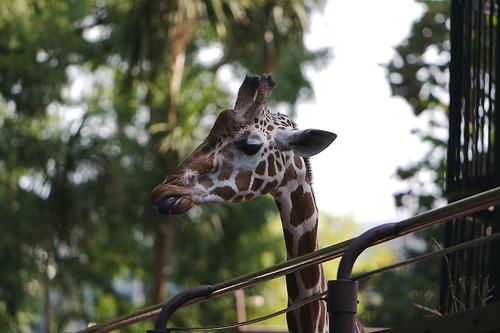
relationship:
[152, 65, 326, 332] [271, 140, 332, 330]
animal has neck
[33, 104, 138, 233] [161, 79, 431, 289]
leaf in front of giraffe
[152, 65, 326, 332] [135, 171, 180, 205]
animal has nose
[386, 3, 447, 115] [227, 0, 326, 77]
leaves on trees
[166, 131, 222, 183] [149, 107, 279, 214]
strip on face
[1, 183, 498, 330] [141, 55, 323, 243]
fene under giraffe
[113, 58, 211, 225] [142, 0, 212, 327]
stem of tree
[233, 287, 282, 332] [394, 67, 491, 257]
wood piece next to cage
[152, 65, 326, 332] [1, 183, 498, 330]
animal looking over fene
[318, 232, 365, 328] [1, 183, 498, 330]
pole of fene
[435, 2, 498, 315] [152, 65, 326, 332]
cage behind animal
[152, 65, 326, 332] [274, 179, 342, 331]
animal has neck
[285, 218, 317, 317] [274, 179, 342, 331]
brown spots on neck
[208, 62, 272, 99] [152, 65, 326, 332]
horn on animal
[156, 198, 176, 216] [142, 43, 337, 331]
black tongue sticking out of giraffe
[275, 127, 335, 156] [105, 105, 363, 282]
ear of giraffe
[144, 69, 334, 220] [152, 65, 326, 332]
head of animal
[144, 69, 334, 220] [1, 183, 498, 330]
head over fene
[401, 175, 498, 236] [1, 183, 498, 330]
rail on fene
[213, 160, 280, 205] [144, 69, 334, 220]
spots on head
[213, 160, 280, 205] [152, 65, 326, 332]
spots on animal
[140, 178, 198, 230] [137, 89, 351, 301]
black tongue hanging out of giraffe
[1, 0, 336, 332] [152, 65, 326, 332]
trees growing behind animal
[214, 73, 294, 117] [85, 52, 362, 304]
horns of giraffe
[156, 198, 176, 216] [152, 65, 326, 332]
black tongue of animal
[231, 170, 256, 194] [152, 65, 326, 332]
brown spot on animal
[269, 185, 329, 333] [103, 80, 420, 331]
giraffe neck of giraffe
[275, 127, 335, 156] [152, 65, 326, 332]
ear of animal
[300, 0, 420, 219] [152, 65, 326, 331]
clear sky above animal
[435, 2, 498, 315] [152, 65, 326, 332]
cage next to animal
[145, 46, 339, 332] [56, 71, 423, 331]
photograph in zoo